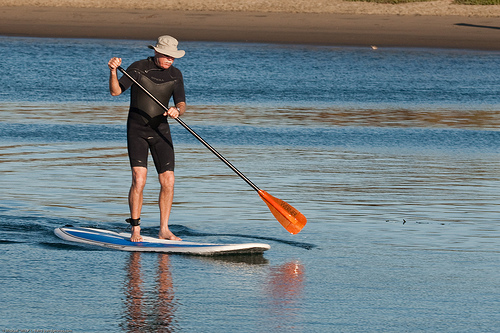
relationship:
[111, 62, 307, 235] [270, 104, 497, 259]
orange paddle almost in water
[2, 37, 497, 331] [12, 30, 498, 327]
body of water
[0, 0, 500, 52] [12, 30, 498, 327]
sand shore at foot of water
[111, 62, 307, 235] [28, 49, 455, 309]
orange paddle almost in water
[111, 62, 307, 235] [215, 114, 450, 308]
orange paddle almost in water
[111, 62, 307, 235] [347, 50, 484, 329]
orange paddle almost in water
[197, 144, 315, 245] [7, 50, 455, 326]
orange paddle almost in water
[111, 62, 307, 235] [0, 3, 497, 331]
orange paddle almost in water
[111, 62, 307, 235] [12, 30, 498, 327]
orange paddle almost in water